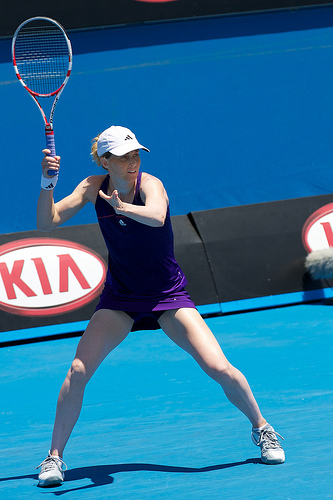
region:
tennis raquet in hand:
[14, 13, 78, 169]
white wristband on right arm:
[39, 177, 66, 192]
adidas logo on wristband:
[45, 179, 55, 189]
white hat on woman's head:
[99, 118, 151, 159]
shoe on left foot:
[253, 427, 300, 472]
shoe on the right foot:
[37, 452, 71, 488]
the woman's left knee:
[213, 361, 238, 380]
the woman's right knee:
[59, 363, 88, 382]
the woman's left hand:
[90, 188, 135, 217]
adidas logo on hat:
[121, 131, 135, 142]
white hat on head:
[97, 123, 154, 153]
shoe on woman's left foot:
[248, 421, 301, 477]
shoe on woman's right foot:
[36, 451, 66, 490]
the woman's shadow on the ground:
[55, 454, 261, 497]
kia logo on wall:
[2, 233, 103, 320]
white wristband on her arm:
[38, 178, 64, 190]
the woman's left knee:
[214, 360, 235, 385]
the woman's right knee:
[66, 359, 82, 384]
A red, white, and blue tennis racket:
[10, 15, 72, 174]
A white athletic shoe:
[250, 423, 286, 465]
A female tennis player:
[35, 124, 285, 487]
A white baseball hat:
[95, 124, 151, 157]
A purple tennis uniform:
[94, 172, 197, 330]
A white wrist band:
[40, 174, 59, 189]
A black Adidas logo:
[43, 181, 54, 189]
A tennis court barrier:
[0, 192, 332, 346]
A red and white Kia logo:
[1, 237, 108, 318]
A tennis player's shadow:
[0, 457, 270, 496]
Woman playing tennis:
[35, 125, 284, 487]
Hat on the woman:
[95, 123, 150, 157]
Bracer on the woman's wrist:
[39, 173, 59, 191]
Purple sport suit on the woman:
[91, 171, 198, 332]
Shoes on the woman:
[35, 423, 285, 486]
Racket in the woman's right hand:
[11, 16, 73, 177]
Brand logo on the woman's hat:
[122, 132, 133, 141]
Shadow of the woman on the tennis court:
[0, 457, 264, 496]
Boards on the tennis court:
[0, 194, 332, 344]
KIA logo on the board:
[0, 237, 107, 316]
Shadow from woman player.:
[70, 456, 253, 484]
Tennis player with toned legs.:
[38, 322, 128, 477]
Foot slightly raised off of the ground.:
[253, 425, 283, 464]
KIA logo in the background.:
[2, 245, 93, 307]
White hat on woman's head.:
[94, 126, 148, 180]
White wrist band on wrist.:
[40, 173, 59, 190]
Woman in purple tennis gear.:
[90, 127, 199, 335]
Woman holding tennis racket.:
[12, 13, 75, 175]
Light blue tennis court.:
[124, 399, 198, 458]